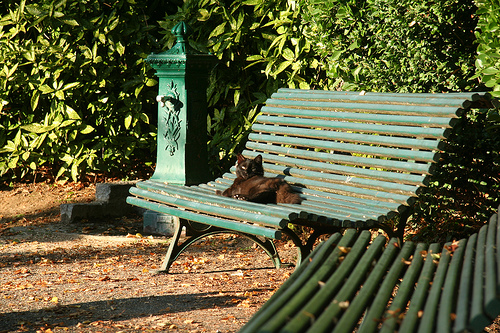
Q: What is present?
A: Benches.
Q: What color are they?
A: Green.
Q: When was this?
A: Daytime.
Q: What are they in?
A: A park.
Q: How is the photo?
A: Clear.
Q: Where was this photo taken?
A: At the park.